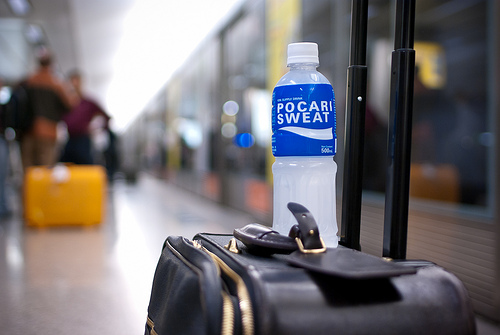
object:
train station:
[0, 0, 500, 335]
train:
[113, 1, 498, 323]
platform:
[3, 153, 281, 334]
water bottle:
[270, 42, 340, 248]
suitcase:
[145, 201, 476, 335]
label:
[274, 92, 333, 143]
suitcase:
[24, 165, 106, 226]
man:
[3, 53, 78, 172]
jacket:
[15, 76, 67, 142]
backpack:
[0, 82, 33, 135]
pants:
[20, 137, 55, 173]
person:
[61, 68, 111, 164]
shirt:
[62, 95, 109, 136]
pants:
[60, 132, 95, 165]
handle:
[231, 202, 323, 253]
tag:
[285, 243, 415, 286]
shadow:
[306, 272, 404, 308]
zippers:
[175, 229, 254, 335]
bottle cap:
[286, 41, 322, 61]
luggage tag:
[51, 164, 71, 183]